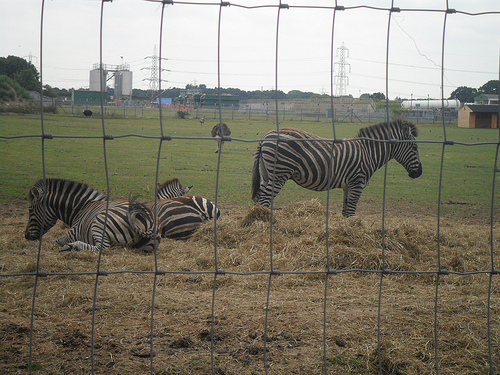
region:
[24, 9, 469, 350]
photograph taken at a zoo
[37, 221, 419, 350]
yellow hay covering the ground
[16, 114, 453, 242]
three black and white zebras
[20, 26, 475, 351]
silver chian link fence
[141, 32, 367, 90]
two tall electricty towers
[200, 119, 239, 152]
brown ostrich in field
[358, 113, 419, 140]
hair on zebras head and neck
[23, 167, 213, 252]
zeras laying in hay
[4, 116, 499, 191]
large green field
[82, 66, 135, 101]
while farm silos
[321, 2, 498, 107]
Section of fence made with thin gray wire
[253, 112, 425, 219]
A zebra standing in brown straw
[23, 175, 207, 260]
A pair of zebras lying in brown grass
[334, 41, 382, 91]
Power lanes and a support structure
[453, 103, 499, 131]
A one-story garage building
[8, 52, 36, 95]
Short, wide, leafy trees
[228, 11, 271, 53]
A portion of gray, empty sky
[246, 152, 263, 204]
A black animal tail hanging down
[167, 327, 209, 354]
Animal poop sitting in a pile on the ground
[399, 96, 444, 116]
A long, thin metal tank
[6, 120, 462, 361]
animals on a pasture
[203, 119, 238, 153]
bird standing on ground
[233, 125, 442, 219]
zebra facing one direction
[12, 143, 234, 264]
zebras sitting on the ground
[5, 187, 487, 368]
brown grass area where zebras rest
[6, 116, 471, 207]
green area of the lawn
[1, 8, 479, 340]
wires of a fence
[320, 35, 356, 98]
tower behind the pasture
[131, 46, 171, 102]
tower behind the pasture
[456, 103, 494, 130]
house on the grass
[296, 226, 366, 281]
hay on the ground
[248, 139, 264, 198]
black tail on the zebra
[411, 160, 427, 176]
black nose on the zebra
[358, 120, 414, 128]
mane of hair on zebra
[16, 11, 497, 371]
grey fence around zebras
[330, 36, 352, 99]
tall tower in the background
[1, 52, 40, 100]
trees on the land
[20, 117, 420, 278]
A group of zebras in a field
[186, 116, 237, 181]
A large bird behind the zebra's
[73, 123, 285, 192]
A field of grass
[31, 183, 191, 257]
Two zebras laying on some hay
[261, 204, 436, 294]
A large pile of hay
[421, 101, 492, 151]
Eights hand and brown building in the distance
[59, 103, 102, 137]
A cow in the field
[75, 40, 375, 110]
A set of powerlines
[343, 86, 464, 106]
A large white tank in the distant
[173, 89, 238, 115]
A green building in the distance